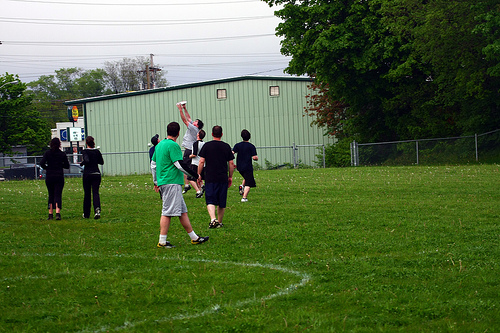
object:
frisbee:
[176, 101, 188, 105]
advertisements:
[66, 105, 82, 163]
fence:
[0, 166, 500, 333]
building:
[63, 75, 339, 175]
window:
[268, 86, 283, 97]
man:
[175, 101, 204, 198]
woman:
[39, 139, 70, 221]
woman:
[78, 136, 104, 220]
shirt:
[150, 137, 184, 188]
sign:
[67, 106, 79, 123]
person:
[232, 129, 258, 203]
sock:
[159, 234, 167, 246]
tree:
[0, 69, 112, 156]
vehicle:
[0, 163, 46, 179]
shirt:
[191, 140, 207, 167]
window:
[216, 89, 228, 99]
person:
[39, 138, 70, 220]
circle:
[5, 245, 312, 329]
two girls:
[37, 135, 104, 220]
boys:
[149, 121, 209, 249]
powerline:
[1, 32, 305, 82]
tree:
[265, 0, 500, 161]